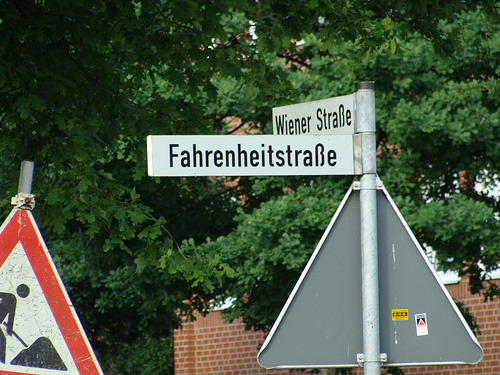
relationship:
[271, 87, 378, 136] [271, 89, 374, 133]
sign on sign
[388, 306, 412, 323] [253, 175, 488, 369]
sticker on sign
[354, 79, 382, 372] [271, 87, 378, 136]
pole holding sign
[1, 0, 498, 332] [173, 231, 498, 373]
tree on wall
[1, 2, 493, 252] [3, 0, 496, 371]
leaves on tree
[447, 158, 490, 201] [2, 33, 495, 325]
branch on tree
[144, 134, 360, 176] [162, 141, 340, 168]
sign show marks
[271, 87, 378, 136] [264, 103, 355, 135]
sign has name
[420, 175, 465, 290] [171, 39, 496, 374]
window on house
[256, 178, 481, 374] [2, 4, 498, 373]
signs in neighborhood